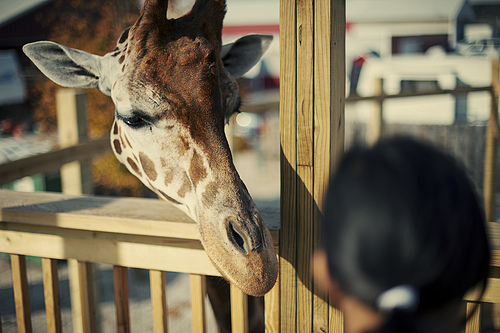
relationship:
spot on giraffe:
[110, 120, 122, 136] [22, 2, 279, 297]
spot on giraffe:
[110, 138, 124, 157] [22, 2, 279, 297]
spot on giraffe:
[119, 127, 135, 150] [22, 2, 279, 297]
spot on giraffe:
[120, 131, 137, 151] [22, 2, 279, 297]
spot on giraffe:
[125, 155, 142, 178] [22, 2, 279, 297]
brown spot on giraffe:
[136, 151, 158, 182] [22, 2, 279, 297]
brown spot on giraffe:
[160, 157, 177, 187] [22, 2, 279, 297]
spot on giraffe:
[174, 169, 193, 202] [22, 2, 279, 297]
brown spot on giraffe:
[189, 149, 208, 186] [22, 2, 279, 297]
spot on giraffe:
[176, 132, 192, 158] [22, 2, 279, 297]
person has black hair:
[304, 129, 484, 330] [322, 132, 484, 331]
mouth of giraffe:
[210, 251, 273, 307] [1, 0, 273, 323]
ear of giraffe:
[19, 33, 95, 98] [1, 0, 273, 323]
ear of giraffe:
[224, 22, 278, 87] [1, 0, 273, 323]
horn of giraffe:
[184, 0, 227, 40] [1, 0, 273, 323]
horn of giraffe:
[139, 0, 177, 36] [1, 0, 273, 323]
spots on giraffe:
[106, 122, 211, 212] [1, 0, 273, 323]